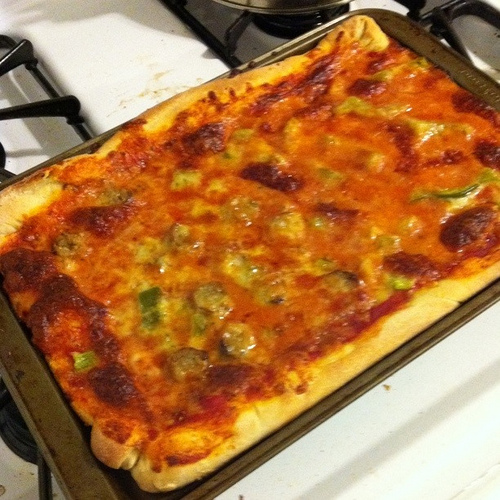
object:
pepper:
[135, 287, 168, 328]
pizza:
[0, 19, 500, 489]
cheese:
[4, 15, 499, 498]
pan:
[0, 0, 494, 497]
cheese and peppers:
[0, 44, 500, 461]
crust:
[0, 14, 500, 485]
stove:
[0, 1, 497, 500]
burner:
[0, 26, 98, 186]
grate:
[161, 0, 353, 69]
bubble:
[439, 206, 494, 249]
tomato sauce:
[0, 45, 498, 472]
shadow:
[0, 0, 210, 62]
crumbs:
[114, 68, 201, 111]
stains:
[382, 15, 454, 65]